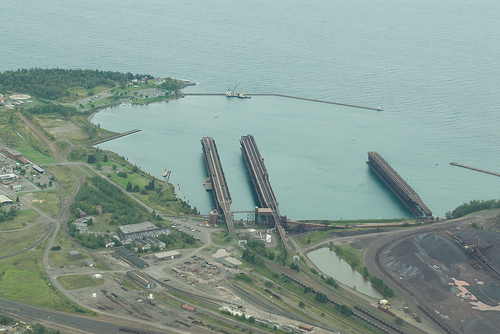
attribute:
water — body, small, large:
[251, 103, 370, 180]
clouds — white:
[47, 5, 108, 31]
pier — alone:
[452, 159, 488, 176]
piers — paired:
[197, 122, 279, 223]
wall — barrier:
[255, 90, 353, 112]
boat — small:
[228, 89, 253, 111]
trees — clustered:
[33, 75, 62, 97]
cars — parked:
[183, 224, 205, 241]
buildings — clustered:
[115, 228, 162, 284]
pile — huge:
[398, 228, 442, 274]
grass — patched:
[300, 229, 346, 245]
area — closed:
[203, 83, 233, 112]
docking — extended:
[183, 76, 191, 95]